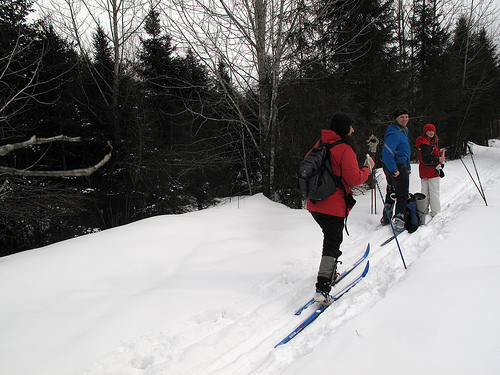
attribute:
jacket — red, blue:
[303, 129, 370, 219]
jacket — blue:
[380, 123, 410, 175]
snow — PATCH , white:
[1, 140, 500, 375]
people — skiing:
[298, 109, 446, 309]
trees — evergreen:
[1, 1, 498, 259]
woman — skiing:
[297, 107, 370, 317]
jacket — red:
[415, 132, 444, 181]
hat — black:
[390, 104, 412, 119]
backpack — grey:
[292, 136, 351, 207]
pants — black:
[311, 209, 342, 292]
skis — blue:
[269, 241, 377, 348]